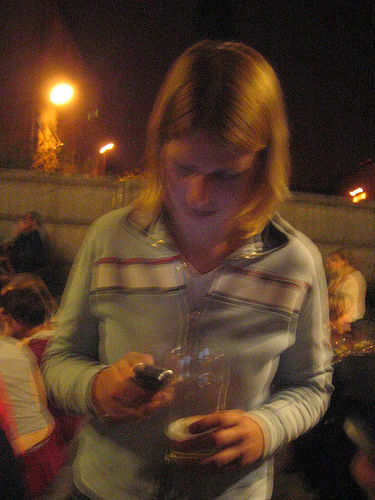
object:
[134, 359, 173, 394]
phone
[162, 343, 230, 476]
glass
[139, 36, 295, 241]
hair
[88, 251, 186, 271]
stripes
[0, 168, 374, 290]
fence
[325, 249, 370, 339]
person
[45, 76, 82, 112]
light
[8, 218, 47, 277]
guy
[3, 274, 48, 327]
hair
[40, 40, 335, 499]
girl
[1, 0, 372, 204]
sky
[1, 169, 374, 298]
wall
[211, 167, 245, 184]
eye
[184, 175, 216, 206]
nose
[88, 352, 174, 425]
hand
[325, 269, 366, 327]
shirt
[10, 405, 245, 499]
down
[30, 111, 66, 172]
tree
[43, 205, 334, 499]
jacket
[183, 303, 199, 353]
zipper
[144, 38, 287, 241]
head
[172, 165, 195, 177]
eyes